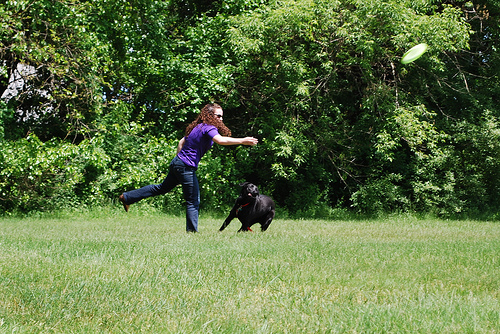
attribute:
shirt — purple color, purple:
[178, 121, 219, 170]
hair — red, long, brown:
[184, 102, 231, 135]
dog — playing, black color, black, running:
[221, 183, 275, 233]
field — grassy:
[4, 213, 500, 334]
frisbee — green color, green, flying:
[404, 41, 425, 64]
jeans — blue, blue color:
[125, 157, 200, 231]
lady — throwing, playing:
[119, 102, 258, 229]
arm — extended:
[211, 128, 257, 147]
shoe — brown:
[119, 190, 130, 211]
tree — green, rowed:
[160, 1, 453, 220]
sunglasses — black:
[213, 113, 223, 119]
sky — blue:
[6, 59, 55, 121]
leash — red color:
[235, 199, 254, 230]